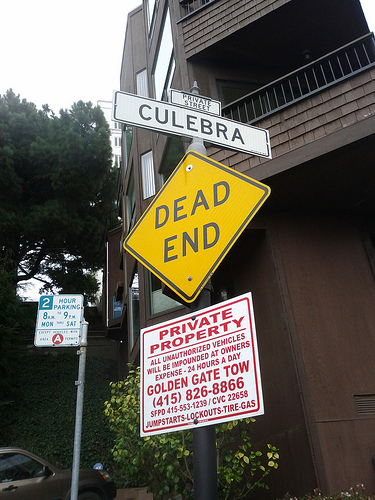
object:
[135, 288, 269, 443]
sign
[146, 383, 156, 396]
writing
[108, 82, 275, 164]
street sign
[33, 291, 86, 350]
sign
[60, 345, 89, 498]
post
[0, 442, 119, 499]
vehicle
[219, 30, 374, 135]
railing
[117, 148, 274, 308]
sign